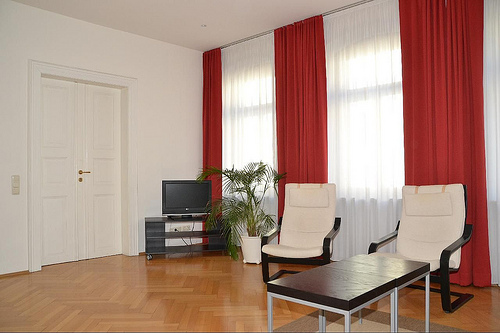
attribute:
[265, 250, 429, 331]
table — white, wooden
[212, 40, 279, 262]
curtain — long sheer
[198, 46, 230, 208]
curtain — long, red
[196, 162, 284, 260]
bush — green, small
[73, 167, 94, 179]
handle — fancy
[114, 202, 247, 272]
stand — black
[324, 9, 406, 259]
curtain — white, long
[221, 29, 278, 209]
curtains — white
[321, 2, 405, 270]
curtains — white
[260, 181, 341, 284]
chair — white, wooden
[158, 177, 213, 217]
tv — off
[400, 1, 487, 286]
curtain — long, red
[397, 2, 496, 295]
curtain — red, long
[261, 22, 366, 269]
curtain — red, long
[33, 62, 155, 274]
doors — double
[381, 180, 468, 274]
chair — white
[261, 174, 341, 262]
chair — white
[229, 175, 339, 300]
chair — white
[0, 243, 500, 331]
floor — wooden, brown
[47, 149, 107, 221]
handle — gold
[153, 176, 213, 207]
tv — flat screen, corner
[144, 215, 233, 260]
cabinet — electronic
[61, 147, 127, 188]
knobs — bronze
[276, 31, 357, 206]
curtain — red, long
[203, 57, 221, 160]
red drape — long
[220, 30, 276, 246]
curtain — long, white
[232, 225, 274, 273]
pot — white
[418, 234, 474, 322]
handle — black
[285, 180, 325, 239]
top — white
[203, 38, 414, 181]
curtain — long, sheer drapery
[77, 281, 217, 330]
floor — wood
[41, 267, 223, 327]
design — herringbone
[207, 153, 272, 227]
palm — potted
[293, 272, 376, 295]
top — dark